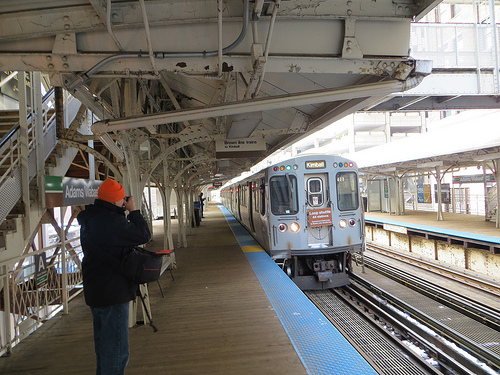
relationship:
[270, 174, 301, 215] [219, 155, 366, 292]
window on train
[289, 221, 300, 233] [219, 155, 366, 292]
headlight on train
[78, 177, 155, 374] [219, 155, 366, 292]
person waiting for train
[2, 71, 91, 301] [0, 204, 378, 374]
stairs next to platform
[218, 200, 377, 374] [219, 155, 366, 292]
blue line near train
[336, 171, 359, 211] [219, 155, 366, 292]
window on train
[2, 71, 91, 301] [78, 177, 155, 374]
stairs behind person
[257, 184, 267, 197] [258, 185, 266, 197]
head of person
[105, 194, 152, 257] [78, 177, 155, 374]
arm of person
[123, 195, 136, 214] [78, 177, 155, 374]
hand of person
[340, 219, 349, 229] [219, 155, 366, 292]
headlight on train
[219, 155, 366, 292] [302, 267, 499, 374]
train on tracks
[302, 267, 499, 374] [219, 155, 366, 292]
tracks in front of train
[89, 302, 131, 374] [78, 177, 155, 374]
jeans on person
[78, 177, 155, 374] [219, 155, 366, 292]
person taking picture of train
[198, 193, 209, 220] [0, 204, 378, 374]
person standing on platform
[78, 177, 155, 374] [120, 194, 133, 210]
person using camera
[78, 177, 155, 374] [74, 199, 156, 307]
person wearing black jacket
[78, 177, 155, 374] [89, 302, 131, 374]
person wearing jeans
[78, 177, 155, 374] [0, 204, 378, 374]
person standing on platform